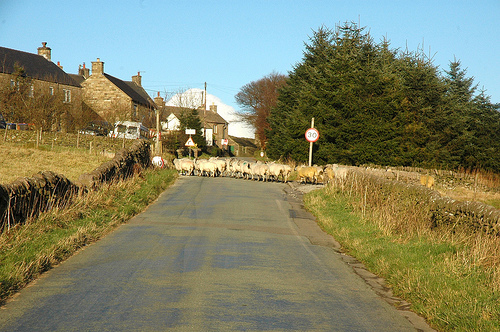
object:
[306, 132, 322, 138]
30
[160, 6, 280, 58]
clouds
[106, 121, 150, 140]
bus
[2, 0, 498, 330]
country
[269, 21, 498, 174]
trees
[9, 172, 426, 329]
road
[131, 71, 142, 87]
chimney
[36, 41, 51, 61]
chimney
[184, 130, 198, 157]
signs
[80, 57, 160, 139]
brick building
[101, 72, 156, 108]
roof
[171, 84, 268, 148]
clouds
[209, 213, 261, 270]
dirt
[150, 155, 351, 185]
animals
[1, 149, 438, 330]
road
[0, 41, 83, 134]
building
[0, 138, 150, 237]
fence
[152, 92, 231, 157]
house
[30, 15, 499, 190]
distance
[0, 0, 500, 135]
sky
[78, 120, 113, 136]
cars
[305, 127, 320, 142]
sign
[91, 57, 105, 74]
chimney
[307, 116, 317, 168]
pole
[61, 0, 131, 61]
clouds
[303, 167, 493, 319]
field